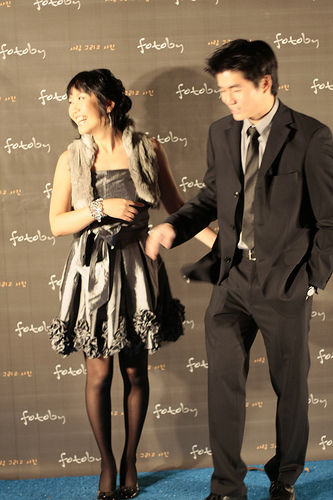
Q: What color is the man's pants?
A: Black.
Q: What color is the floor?
A: Blue.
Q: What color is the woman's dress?
A: Gray.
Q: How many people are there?
A: Two.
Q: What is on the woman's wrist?
A: A Bracelet.